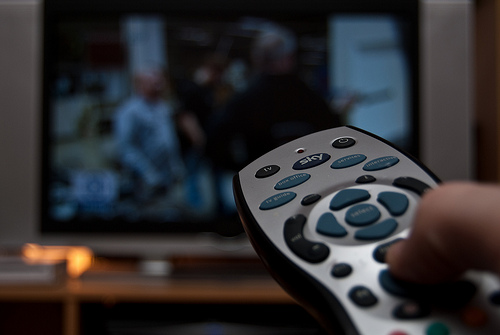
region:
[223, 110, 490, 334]
thumb on a remote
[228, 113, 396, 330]
remote with blue and black buttons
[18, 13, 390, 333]
remote aimed at televison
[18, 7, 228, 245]
flat screened tv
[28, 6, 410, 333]
tv with remote aimed at it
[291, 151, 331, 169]
black button with white writing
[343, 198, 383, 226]
blue button with white writing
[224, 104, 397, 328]
black and silver remote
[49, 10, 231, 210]
blurry tv picture in color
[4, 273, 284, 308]
top of wood shelf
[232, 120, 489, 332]
The remote is silver.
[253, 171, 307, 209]
The buttons are blue.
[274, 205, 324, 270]
The buttons are black.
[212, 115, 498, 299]
A person is holding the remote.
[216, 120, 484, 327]
The person is pressing a button.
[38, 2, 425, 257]
The TV is on.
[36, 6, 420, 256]
The TV is black.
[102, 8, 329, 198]
The people are on the TV.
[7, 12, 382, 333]
The TV is on a table.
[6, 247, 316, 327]
The table is brown.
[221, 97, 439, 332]
silver tv remote in hand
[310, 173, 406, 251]
blue rubber buttons on remote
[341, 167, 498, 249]
person's thumb on button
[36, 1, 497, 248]
flat screen tv in background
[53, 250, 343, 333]
wooden tv stand in background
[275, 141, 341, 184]
black sky button on remote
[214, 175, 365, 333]
black border on silver remote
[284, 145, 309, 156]
small power light on remote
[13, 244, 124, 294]
light reflecting on stand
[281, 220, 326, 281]
black buttons on remote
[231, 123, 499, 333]
silver remote control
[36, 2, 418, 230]
television set is on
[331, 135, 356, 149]
power button on remote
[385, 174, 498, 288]
finger pushing remote button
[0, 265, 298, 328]
wooden entertainment center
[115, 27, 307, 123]
two people on television set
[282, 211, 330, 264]
volume button on remote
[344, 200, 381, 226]
round blue select button on remote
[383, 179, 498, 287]
thumb is bent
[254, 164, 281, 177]
tv button on remote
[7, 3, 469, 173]
this is a TV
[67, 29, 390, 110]
the TV is on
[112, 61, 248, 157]
these are some people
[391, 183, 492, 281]
this is a finger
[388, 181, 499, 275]
the finger is big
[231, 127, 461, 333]
this is a remote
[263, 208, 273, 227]
the area is grey in color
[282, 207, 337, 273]
the buttons are black in color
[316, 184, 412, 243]
the buttons are blue in color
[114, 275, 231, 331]
this is a TV cabinet